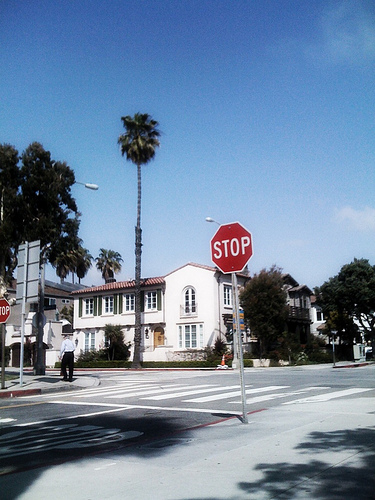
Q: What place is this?
A: It is a pavement.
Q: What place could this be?
A: It is a pavement.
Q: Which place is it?
A: It is a pavement.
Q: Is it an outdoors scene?
A: Yes, it is outdoors.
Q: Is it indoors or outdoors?
A: It is outdoors.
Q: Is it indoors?
A: No, it is outdoors.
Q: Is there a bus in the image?
A: No, there are no buses.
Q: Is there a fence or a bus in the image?
A: No, there are no buses or fences.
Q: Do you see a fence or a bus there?
A: No, there are no buses or fences.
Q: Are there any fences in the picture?
A: No, there are no fences.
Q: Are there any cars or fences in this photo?
A: No, there are no fences or cars.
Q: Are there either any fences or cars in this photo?
A: No, there are no fences or cars.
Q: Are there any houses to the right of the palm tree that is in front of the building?
A: Yes, there is a house to the right of the palm tree.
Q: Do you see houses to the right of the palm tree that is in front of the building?
A: Yes, there is a house to the right of the palm tree.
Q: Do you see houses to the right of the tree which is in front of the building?
A: Yes, there is a house to the right of the palm tree.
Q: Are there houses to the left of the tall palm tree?
A: No, the house is to the right of the palm.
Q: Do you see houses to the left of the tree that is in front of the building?
A: No, the house is to the right of the palm.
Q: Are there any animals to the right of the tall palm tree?
A: No, there is a house to the right of the palm tree.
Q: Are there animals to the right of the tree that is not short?
A: No, there is a house to the right of the palm tree.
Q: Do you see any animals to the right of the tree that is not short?
A: No, there is a house to the right of the palm tree.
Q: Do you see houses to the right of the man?
A: Yes, there is a house to the right of the man.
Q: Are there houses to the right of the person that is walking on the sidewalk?
A: Yes, there is a house to the right of the man.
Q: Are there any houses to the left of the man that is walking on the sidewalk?
A: No, the house is to the right of the man.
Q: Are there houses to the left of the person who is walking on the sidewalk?
A: No, the house is to the right of the man.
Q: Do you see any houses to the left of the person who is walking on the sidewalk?
A: No, the house is to the right of the man.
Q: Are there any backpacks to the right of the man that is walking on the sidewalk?
A: No, there is a house to the right of the man.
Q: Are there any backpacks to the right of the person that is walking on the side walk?
A: No, there is a house to the right of the man.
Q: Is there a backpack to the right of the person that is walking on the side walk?
A: No, there is a house to the right of the man.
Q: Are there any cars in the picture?
A: No, there are no cars.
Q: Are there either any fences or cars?
A: No, there are no cars or fences.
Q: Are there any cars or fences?
A: No, there are no cars or fences.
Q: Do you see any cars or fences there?
A: No, there are no cars or fences.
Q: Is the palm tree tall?
A: Yes, the palm tree is tall.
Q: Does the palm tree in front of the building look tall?
A: Yes, the palm is tall.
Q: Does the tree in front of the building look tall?
A: Yes, the palm is tall.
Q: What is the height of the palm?
A: The palm is tall.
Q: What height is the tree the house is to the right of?
A: The palm is tall.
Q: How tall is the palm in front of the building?
A: The palm tree is tall.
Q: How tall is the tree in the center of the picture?
A: The palm tree is tall.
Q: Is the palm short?
A: No, the palm is tall.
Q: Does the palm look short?
A: No, the palm is tall.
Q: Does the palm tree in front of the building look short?
A: No, the palm is tall.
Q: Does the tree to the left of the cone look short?
A: No, the palm is tall.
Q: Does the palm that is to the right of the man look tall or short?
A: The palm is tall.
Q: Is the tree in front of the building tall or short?
A: The palm is tall.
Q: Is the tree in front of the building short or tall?
A: The palm is tall.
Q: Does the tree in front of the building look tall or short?
A: The palm is tall.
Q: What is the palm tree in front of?
A: The palm tree is in front of the building.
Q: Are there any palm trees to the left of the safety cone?
A: Yes, there is a palm tree to the left of the safety cone.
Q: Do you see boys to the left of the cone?
A: No, there is a palm tree to the left of the cone.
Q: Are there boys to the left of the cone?
A: No, there is a palm tree to the left of the cone.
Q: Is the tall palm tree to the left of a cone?
A: Yes, the palm is to the left of a cone.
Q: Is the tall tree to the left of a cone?
A: Yes, the palm is to the left of a cone.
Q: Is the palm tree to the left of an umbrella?
A: No, the palm tree is to the left of a cone.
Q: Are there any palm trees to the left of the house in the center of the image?
A: Yes, there is a palm tree to the left of the house.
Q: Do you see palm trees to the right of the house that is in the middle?
A: No, the palm tree is to the left of the house.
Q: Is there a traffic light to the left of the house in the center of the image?
A: No, there is a palm tree to the left of the house.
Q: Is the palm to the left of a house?
A: Yes, the palm is to the left of a house.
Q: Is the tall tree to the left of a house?
A: Yes, the palm is to the left of a house.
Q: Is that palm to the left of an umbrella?
A: No, the palm is to the left of a house.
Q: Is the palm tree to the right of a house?
A: No, the palm tree is to the left of a house.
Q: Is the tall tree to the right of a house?
A: No, the palm tree is to the left of a house.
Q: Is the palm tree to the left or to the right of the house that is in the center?
A: The palm tree is to the left of the house.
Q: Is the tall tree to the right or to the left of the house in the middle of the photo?
A: The palm tree is to the left of the house.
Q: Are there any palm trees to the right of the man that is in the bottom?
A: Yes, there is a palm tree to the right of the man.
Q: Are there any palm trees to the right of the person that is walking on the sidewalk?
A: Yes, there is a palm tree to the right of the man.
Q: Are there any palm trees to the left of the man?
A: No, the palm tree is to the right of the man.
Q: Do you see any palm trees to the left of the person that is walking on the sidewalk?
A: No, the palm tree is to the right of the man.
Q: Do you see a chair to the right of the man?
A: No, there is a palm tree to the right of the man.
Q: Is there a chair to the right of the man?
A: No, there is a palm tree to the right of the man.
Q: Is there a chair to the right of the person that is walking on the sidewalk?
A: No, there is a palm tree to the right of the man.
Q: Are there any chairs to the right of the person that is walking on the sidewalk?
A: No, there is a palm tree to the right of the man.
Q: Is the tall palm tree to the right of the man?
A: Yes, the palm tree is to the right of the man.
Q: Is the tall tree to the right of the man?
A: Yes, the palm tree is to the right of the man.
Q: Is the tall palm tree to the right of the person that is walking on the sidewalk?
A: Yes, the palm tree is to the right of the man.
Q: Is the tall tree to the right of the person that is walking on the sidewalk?
A: Yes, the palm tree is to the right of the man.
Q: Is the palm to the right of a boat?
A: No, the palm is to the right of the man.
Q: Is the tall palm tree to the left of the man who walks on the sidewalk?
A: No, the palm is to the right of the man.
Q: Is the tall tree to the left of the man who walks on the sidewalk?
A: No, the palm is to the right of the man.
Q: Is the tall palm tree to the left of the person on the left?
A: No, the palm is to the right of the man.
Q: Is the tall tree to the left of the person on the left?
A: No, the palm is to the right of the man.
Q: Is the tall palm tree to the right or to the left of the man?
A: The palm is to the right of the man.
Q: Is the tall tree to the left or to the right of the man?
A: The palm is to the right of the man.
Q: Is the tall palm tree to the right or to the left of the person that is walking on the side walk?
A: The palm is to the right of the man.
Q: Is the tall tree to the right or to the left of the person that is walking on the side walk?
A: The palm is to the right of the man.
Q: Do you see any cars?
A: No, there are no cars.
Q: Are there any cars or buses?
A: No, there are no cars or buses.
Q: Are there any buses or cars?
A: No, there are no cars or buses.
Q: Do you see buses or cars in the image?
A: No, there are no cars or buses.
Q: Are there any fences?
A: No, there are no fences.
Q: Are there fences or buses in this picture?
A: No, there are no fences or buses.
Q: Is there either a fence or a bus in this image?
A: No, there are no fences or buses.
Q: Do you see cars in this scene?
A: No, there are no cars.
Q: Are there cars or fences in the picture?
A: No, there are no cars or fences.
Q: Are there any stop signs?
A: Yes, there is a stop sign.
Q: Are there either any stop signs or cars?
A: Yes, there is a stop sign.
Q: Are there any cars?
A: No, there are no cars.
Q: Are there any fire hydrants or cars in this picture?
A: No, there are no cars or fire hydrants.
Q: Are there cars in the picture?
A: No, there are no cars.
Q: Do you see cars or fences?
A: No, there are no cars or fences.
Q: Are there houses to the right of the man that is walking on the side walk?
A: Yes, there is a house to the right of the man.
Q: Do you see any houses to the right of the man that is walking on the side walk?
A: Yes, there is a house to the right of the man.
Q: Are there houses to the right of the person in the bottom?
A: Yes, there is a house to the right of the man.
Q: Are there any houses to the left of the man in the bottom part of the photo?
A: No, the house is to the right of the man.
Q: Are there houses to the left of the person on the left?
A: No, the house is to the right of the man.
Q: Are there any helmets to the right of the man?
A: No, there is a house to the right of the man.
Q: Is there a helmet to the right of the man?
A: No, there is a house to the right of the man.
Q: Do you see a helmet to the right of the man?
A: No, there is a house to the right of the man.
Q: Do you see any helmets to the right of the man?
A: No, there is a house to the right of the man.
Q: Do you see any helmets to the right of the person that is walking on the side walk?
A: No, there is a house to the right of the man.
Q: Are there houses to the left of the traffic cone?
A: Yes, there is a house to the left of the traffic cone.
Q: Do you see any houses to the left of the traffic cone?
A: Yes, there is a house to the left of the traffic cone.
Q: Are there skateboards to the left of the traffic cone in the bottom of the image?
A: No, there is a house to the left of the traffic cone.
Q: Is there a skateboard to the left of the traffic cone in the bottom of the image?
A: No, there is a house to the left of the traffic cone.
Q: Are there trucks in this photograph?
A: No, there are no trucks.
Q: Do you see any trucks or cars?
A: No, there are no trucks or cars.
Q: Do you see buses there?
A: No, there are no buses.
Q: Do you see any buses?
A: No, there are no buses.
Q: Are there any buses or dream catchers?
A: No, there are no buses or dream catchers.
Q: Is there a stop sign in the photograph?
A: Yes, there is a stop sign.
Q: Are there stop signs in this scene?
A: Yes, there is a stop sign.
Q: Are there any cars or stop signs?
A: Yes, there is a stop sign.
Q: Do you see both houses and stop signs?
A: Yes, there are both a stop sign and a house.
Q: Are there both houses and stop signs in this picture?
A: Yes, there are both a stop sign and a house.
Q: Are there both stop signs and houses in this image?
A: Yes, there are both a stop sign and a house.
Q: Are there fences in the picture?
A: No, there are no fences.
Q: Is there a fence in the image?
A: No, there are no fences.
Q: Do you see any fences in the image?
A: No, there are no fences.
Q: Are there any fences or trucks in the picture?
A: No, there are no fences or trucks.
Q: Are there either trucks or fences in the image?
A: No, there are no fences or trucks.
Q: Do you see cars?
A: No, there are no cars.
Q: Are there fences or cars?
A: No, there are no cars or fences.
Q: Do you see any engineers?
A: No, there are no engineers.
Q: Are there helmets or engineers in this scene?
A: No, there are no engineers or helmets.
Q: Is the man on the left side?
A: Yes, the man is on the left of the image.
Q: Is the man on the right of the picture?
A: No, the man is on the left of the image.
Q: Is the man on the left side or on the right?
A: The man is on the left of the image.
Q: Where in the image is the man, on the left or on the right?
A: The man is on the left of the image.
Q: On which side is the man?
A: The man is on the left of the image.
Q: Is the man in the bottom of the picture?
A: Yes, the man is in the bottom of the image.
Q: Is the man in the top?
A: No, the man is in the bottom of the image.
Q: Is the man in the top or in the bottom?
A: The man is in the bottom of the image.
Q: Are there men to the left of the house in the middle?
A: Yes, there is a man to the left of the house.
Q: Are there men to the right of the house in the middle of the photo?
A: No, the man is to the left of the house.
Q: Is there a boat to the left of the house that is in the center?
A: No, there is a man to the left of the house.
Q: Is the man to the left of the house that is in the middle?
A: Yes, the man is to the left of the house.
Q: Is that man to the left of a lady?
A: No, the man is to the left of the house.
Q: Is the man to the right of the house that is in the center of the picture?
A: No, the man is to the left of the house.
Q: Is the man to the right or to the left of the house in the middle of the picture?
A: The man is to the left of the house.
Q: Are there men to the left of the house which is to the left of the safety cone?
A: Yes, there is a man to the left of the house.